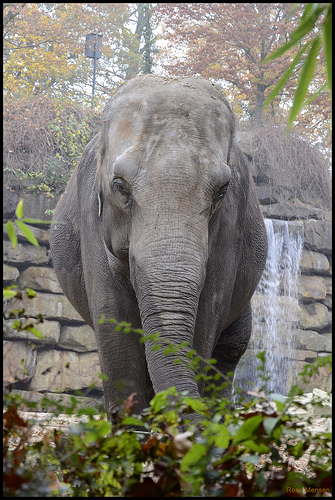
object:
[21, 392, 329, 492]
bush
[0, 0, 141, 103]
orange trees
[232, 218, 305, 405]
waterfall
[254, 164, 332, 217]
rocks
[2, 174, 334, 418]
wall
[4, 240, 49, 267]
stone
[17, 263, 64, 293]
stone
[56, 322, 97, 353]
stone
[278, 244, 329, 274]
stone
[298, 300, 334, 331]
stone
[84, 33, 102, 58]
sign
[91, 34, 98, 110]
post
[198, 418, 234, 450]
leaves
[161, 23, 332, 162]
trees